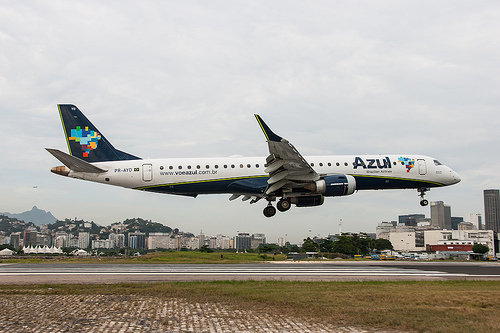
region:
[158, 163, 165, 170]
small window on plane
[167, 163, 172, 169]
small window on plane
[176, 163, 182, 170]
small window on plane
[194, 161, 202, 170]
small window on plane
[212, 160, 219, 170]
small window on plane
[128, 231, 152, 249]
a building in a distance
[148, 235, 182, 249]
a building in a distance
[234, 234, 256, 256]
a building in a distance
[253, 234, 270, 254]
a building in a distance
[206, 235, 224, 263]
a building in a distance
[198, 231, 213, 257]
a building in a distance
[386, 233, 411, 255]
a building in a distance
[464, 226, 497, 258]
a building in a distance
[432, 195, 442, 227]
a building in a distance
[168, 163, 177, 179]
a window on a plane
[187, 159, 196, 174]
a window on a plane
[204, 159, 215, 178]
a window on a plane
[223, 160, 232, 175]
a window on a plane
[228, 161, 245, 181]
a window on a plane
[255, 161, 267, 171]
a window on a plane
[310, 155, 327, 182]
a window on a plane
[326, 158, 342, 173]
a window on a plane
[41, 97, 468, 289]
this is a plane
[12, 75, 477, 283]
the plane is white and blue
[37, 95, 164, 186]
the tail is dark blue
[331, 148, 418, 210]
the text says AZUL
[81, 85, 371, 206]
this is a commercial flight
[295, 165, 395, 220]
these are plane engines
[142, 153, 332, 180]
these are windows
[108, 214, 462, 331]
this is a runway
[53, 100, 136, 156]
tail of plane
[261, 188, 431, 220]
wheels of plane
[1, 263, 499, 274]
a landing strip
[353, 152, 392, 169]
azul on side of plane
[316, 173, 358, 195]
engine on the right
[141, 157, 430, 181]
doors on the body of plane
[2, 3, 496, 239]
a cloudy sky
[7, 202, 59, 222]
hill in horizon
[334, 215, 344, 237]
a tower in back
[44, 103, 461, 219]
Airplane is landing.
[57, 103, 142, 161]
Tail of the airplane.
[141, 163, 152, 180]
Door near the back of the airplane.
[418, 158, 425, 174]
Door front the back of the airplane.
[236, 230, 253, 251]
A building in a city.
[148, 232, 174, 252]
A building in a city.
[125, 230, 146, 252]
A building in a city.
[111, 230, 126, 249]
A building in a city.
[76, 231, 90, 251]
A building in a city.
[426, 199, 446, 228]
A building in a city.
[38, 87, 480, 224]
airplane flying in the air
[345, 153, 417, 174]
name of an airline company on a plane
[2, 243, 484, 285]
tarmac for airplanes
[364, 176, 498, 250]
skyline of buildings in the background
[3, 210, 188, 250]
three hills behind a group of buildings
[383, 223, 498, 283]
buildings next to a tarmac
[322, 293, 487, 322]
patch of yellow and green grass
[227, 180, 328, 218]
landing gear on an aircraft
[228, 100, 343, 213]
wing of airplane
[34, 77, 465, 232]
a plane in the air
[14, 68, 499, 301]
the plane approaching a landing